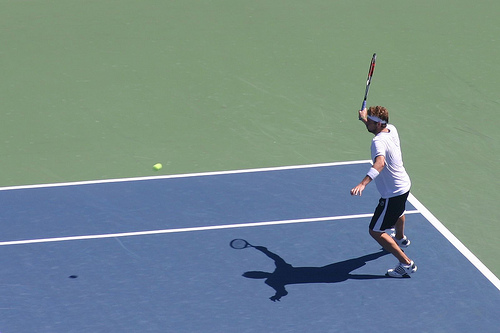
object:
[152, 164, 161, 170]
ball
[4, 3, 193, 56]
air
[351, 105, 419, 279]
man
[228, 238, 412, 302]
shadow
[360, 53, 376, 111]
racket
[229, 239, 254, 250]
shadow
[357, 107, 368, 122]
man's hand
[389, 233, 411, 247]
tennis shoe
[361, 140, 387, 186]
left arm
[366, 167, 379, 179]
wristband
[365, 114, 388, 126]
headband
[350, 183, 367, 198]
left hand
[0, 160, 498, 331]
tennis court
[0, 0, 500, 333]
court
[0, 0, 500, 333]
ground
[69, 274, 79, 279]
shadow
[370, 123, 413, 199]
shirt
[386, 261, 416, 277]
tennis shoes